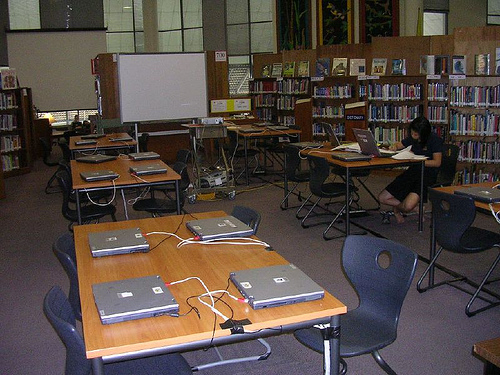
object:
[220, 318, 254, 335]
black tape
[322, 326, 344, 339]
black tape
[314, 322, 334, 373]
wires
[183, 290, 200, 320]
wires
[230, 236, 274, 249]
wires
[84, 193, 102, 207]
wires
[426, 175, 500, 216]
table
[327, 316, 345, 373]
leg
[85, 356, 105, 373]
leg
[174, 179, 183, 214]
leg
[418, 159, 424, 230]
leg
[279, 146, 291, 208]
leg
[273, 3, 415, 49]
wall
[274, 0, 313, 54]
painting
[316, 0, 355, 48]
painting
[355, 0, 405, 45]
painting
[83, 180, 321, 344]
frosting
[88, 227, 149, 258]
computer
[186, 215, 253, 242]
computer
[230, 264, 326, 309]
computer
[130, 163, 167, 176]
computer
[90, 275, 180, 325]
computer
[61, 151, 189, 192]
table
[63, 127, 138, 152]
table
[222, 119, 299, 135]
table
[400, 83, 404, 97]
books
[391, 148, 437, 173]
ground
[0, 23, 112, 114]
screen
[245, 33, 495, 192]
cases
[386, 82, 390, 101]
books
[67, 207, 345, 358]
table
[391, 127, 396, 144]
books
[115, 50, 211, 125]
board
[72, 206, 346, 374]
desk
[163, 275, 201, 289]
cord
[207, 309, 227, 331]
cord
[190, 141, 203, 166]
wires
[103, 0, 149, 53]
window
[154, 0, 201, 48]
window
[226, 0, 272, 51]
window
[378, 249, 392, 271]
hole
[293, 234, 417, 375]
chair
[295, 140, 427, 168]
table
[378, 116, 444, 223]
girl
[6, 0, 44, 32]
windows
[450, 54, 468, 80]
book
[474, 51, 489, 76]
book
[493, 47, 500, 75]
book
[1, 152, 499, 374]
carpet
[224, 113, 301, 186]
desk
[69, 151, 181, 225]
desk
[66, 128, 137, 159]
desk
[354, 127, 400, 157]
laptop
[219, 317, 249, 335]
tape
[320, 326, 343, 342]
tape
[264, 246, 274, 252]
tape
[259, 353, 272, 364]
tape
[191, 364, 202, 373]
tape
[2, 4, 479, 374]
library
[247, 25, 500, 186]
book shelves